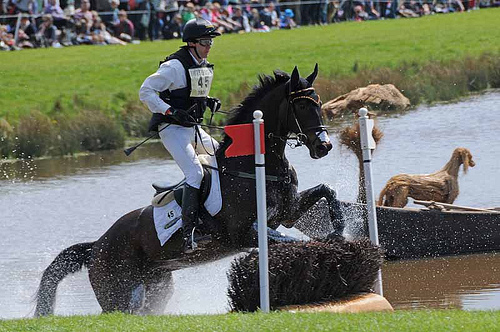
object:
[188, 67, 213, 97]
bib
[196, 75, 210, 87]
number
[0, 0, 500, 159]
field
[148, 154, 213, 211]
saddle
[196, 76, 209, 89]
45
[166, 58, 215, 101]
chest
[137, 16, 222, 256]
man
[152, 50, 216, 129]
vest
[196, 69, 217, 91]
number sign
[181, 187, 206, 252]
boot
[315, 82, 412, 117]
rock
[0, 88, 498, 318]
water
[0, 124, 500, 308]
pond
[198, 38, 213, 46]
goggles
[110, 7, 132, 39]
person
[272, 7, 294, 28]
person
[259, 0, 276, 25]
person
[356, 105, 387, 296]
pole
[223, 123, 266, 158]
flag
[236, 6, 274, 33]
person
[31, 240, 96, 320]
tail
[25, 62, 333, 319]
horse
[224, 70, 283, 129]
hair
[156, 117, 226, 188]
pants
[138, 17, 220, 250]
jockey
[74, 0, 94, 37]
person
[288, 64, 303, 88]
pointed ears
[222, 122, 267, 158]
red flag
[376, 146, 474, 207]
dog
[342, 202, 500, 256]
boat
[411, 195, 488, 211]
paddle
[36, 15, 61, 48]
person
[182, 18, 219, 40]
hat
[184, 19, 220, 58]
head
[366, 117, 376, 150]
flag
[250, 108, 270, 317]
pole